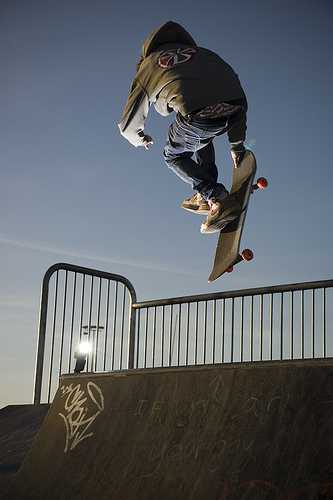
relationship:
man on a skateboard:
[109, 21, 246, 230] [208, 133, 263, 287]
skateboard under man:
[208, 133, 263, 287] [109, 21, 246, 230]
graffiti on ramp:
[50, 382, 298, 485] [12, 364, 330, 499]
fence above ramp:
[27, 262, 332, 374] [12, 364, 330, 499]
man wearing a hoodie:
[109, 21, 246, 230] [116, 17, 245, 153]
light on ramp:
[60, 337, 102, 377] [12, 364, 330, 499]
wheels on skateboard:
[241, 175, 268, 265] [208, 133, 263, 287]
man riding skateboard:
[109, 21, 246, 230] [208, 133, 263, 287]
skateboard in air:
[208, 133, 263, 287] [263, 127, 329, 282]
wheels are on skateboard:
[241, 175, 268, 265] [208, 133, 263, 287]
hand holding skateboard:
[227, 140, 251, 171] [208, 133, 263, 287]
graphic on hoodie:
[146, 45, 205, 69] [116, 17, 245, 153]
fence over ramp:
[27, 262, 332, 374] [12, 364, 330, 499]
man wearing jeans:
[109, 21, 246, 230] [164, 106, 243, 201]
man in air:
[109, 21, 246, 230] [263, 127, 329, 282]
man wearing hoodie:
[109, 21, 246, 230] [116, 17, 245, 153]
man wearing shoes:
[109, 21, 246, 230] [178, 182, 244, 231]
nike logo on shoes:
[204, 202, 230, 217] [178, 182, 244, 231]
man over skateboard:
[109, 21, 246, 230] [208, 133, 263, 287]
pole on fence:
[131, 273, 332, 315] [27, 262, 332, 374]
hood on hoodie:
[139, 15, 201, 53] [116, 17, 245, 153]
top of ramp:
[57, 350, 332, 384] [12, 364, 330, 499]